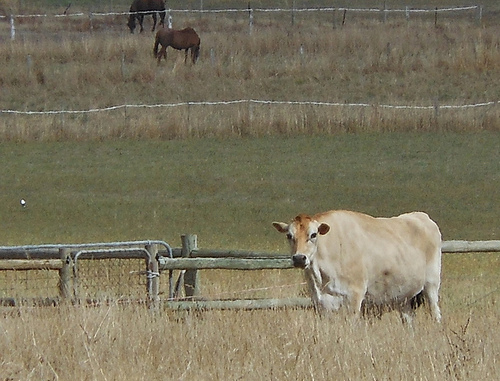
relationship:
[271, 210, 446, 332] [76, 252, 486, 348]
cow in field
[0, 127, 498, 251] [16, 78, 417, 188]
grass in field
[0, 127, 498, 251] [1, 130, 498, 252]
grass in field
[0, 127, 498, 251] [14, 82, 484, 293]
grass in field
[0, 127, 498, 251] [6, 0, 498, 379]
grass in field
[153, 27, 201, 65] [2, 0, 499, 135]
brown horse in pasture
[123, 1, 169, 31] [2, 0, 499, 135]
horse in pasture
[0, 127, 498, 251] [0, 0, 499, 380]
grass in pasture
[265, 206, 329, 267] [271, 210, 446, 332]
head of cow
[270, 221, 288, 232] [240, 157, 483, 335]
ear of cow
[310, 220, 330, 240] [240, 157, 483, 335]
ear of cow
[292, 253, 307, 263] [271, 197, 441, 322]
nose of cow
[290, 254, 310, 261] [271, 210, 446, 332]
nostril of cow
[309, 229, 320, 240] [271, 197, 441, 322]
eye of cow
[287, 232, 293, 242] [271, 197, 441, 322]
eye of cow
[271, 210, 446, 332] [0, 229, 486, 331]
cow in pasture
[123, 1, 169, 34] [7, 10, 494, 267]
horse in pasture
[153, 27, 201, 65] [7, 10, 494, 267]
brown horse in pasture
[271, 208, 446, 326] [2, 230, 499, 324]
cow next to fence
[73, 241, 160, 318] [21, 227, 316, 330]
gate on fence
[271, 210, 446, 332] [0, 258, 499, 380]
cow standing in grass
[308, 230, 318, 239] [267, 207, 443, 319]
black eye on cow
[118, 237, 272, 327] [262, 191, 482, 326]
fence behind cow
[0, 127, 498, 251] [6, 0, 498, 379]
grass growing in field